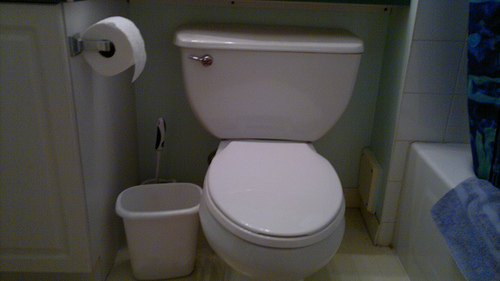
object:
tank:
[182, 42, 355, 138]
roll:
[80, 17, 146, 75]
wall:
[48, 3, 94, 113]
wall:
[196, 7, 347, 23]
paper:
[83, 14, 145, 77]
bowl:
[200, 138, 354, 278]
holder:
[65, 31, 113, 58]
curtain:
[460, 7, 493, 195]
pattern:
[468, 73, 498, 104]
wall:
[385, 2, 473, 265]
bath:
[395, 135, 494, 278]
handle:
[147, 113, 170, 178]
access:
[357, 152, 383, 228]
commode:
[167, 26, 372, 270]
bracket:
[67, 25, 115, 65]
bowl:
[173, 17, 383, 277]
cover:
[207, 134, 341, 251]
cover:
[170, 24, 369, 61]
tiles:
[364, 6, 480, 246]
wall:
[380, 5, 481, 266]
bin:
[109, 179, 220, 279]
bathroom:
[2, 2, 484, 279]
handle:
[187, 49, 218, 68]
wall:
[32, 11, 153, 152]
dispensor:
[61, 31, 111, 60]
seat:
[204, 134, 354, 239]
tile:
[397, 85, 467, 141]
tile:
[379, 178, 399, 218]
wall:
[377, 65, 407, 235]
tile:
[377, 205, 395, 237]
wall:
[355, 129, 407, 249]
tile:
[408, 40, 466, 98]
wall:
[399, 4, 469, 142]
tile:
[413, 7, 493, 45]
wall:
[410, 7, 473, 145]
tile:
[452, 47, 492, 101]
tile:
[433, 89, 473, 145]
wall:
[406, 7, 486, 145]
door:
[6, 9, 93, 279]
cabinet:
[8, 7, 138, 261]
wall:
[66, 74, 142, 175]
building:
[8, 13, 486, 280]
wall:
[22, 107, 127, 188]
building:
[50, 101, 123, 181]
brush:
[149, 115, 170, 183]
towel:
[433, 180, 498, 274]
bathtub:
[403, 141, 499, 280]